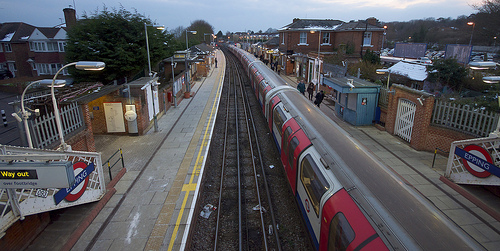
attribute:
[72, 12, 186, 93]
tree — green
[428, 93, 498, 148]
fence — white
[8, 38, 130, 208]
lights — security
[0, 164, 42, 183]
signboard — black yellow & white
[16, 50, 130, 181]
lampposts — gray, large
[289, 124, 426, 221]
trains — public transport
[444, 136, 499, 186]
sign — white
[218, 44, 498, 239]
train — red, white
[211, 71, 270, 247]
train tracks — red, white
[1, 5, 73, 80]
brick building —  Brick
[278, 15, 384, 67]
brick building —  Brick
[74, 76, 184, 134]
brick building —  Brick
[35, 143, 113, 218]
symbol — red blue & white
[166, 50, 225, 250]
line — yellow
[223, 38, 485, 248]
train — long